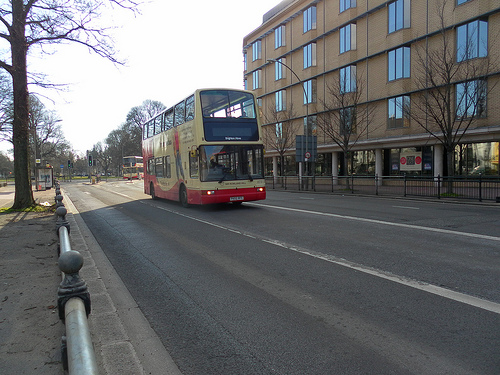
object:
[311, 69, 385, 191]
tree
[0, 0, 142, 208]
tree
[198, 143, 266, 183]
window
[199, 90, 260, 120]
window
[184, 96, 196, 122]
window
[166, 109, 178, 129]
window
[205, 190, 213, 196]
headlights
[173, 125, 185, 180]
ad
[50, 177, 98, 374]
rail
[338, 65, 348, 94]
windows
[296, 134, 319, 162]
sign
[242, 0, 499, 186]
building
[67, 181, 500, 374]
road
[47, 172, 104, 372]
silver/metal fence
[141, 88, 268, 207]
bus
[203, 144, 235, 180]
windshields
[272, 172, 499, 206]
fence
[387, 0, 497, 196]
trees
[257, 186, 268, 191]
headlights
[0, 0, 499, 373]
photo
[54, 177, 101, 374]
fence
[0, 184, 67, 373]
sidewalk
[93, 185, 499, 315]
line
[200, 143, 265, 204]
front view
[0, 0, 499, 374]
ohio